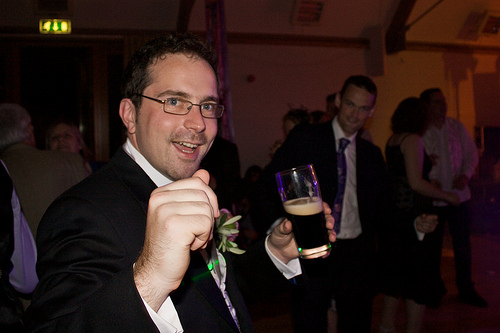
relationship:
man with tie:
[267, 78, 382, 331] [208, 242, 223, 281]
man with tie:
[14, 25, 336, 332] [332, 137, 349, 234]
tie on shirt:
[208, 242, 223, 281] [122, 137, 244, 330]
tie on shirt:
[332, 137, 349, 234] [330, 116, 361, 240]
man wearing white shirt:
[14, 25, 336, 332] [419, 119, 474, 204]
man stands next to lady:
[14, 25, 336, 332] [387, 90, 440, 308]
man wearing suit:
[14, 25, 336, 332] [21, 135, 307, 331]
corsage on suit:
[204, 205, 250, 260] [21, 135, 307, 331]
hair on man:
[127, 27, 250, 128] [14, 25, 336, 332]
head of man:
[126, 48, 226, 162] [14, 25, 336, 332]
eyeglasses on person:
[143, 93, 225, 119] [65, 27, 306, 327]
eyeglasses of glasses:
[143, 93, 225, 119] [141, 98, 223, 115]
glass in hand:
[273, 163, 330, 259] [239, 133, 325, 274]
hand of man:
[255, 149, 369, 330] [28, 32, 268, 331]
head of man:
[335, 77, 379, 136] [267, 78, 387, 332]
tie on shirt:
[332, 137, 349, 234] [324, 120, 363, 235]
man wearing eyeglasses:
[21, 25, 254, 322] [143, 91, 221, 124]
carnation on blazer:
[218, 210, 243, 259] [19, 147, 297, 331]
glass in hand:
[273, 163, 330, 259] [268, 197, 336, 262]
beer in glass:
[283, 197, 329, 250] [273, 163, 330, 259]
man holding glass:
[14, 25, 336, 332] [273, 163, 330, 259]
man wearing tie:
[267, 78, 387, 332] [328, 147, 357, 222]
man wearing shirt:
[267, 78, 387, 332] [320, 120, 391, 260]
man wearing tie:
[267, 78, 387, 332] [321, 120, 370, 251]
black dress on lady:
[387, 144, 444, 301] [382, 95, 460, 329]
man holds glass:
[14, 25, 336, 332] [272, 161, 336, 261]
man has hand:
[14, 25, 336, 332] [143, 167, 226, 306]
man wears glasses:
[14, 25, 336, 332] [138, 95, 223, 120]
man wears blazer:
[14, 25, 336, 332] [19, 147, 297, 331]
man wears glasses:
[14, 25, 336, 332] [129, 90, 224, 117]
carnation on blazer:
[218, 210, 246, 255] [19, 147, 297, 331]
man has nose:
[14, 25, 336, 332] [183, 105, 206, 132]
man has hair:
[14, 25, 336, 332] [127, 27, 221, 105]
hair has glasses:
[127, 27, 221, 105] [138, 91, 225, 124]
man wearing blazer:
[267, 78, 387, 332] [260, 123, 458, 311]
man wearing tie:
[267, 78, 387, 332] [330, 134, 351, 231]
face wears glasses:
[117, 29, 224, 181] [143, 85, 218, 118]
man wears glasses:
[14, 25, 336, 332] [143, 85, 218, 118]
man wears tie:
[267, 78, 387, 332] [330, 130, 360, 242]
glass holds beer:
[273, 163, 330, 259] [289, 195, 333, 254]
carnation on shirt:
[218, 210, 246, 255] [201, 159, 244, 329]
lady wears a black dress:
[377, 95, 460, 332] [382, 140, 442, 302]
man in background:
[415, 86, 485, 308] [227, 4, 496, 167]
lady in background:
[377, 95, 460, 332] [227, 4, 496, 167]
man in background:
[267, 78, 387, 332] [227, 4, 496, 167]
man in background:
[14, 25, 336, 332] [227, 4, 496, 167]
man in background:
[4, 101, 93, 233] [227, 4, 496, 167]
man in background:
[267, 78, 387, 332] [235, 21, 495, 170]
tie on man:
[332, 137, 349, 234] [247, 74, 384, 331]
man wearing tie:
[267, 78, 387, 332] [330, 134, 356, 233]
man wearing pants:
[267, 78, 387, 332] [288, 237, 377, 331]